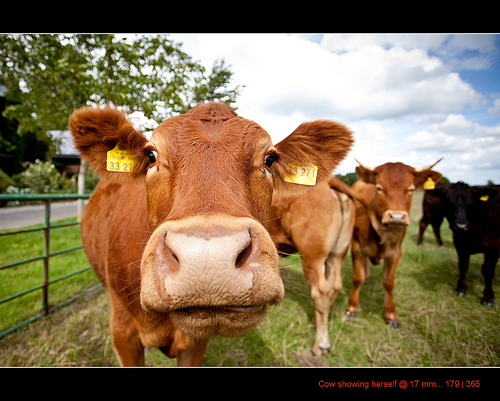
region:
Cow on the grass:
[332, 146, 452, 331]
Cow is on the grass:
[336, 146, 444, 326]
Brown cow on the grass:
[335, 151, 442, 331]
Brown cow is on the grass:
[339, 147, 445, 330]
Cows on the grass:
[61, 85, 498, 365]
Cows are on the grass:
[38, 92, 498, 367]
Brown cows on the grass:
[60, 98, 448, 368]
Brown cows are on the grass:
[57, 97, 447, 372]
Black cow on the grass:
[427, 170, 499, 310]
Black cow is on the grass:
[435, 175, 498, 309]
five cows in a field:
[3, 99, 498, 364]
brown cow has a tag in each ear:
[68, 100, 356, 364]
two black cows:
[415, 178, 499, 308]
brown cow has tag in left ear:
[348, 155, 445, 330]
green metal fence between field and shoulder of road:
[1, 192, 110, 367]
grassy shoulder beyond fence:
[0, 192, 102, 340]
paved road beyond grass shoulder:
[0, 201, 99, 334]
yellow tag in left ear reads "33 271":
[268, 119, 353, 213]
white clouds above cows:
[416, 112, 498, 310]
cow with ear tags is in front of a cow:
[66, 99, 358, 368]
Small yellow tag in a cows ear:
[88, 137, 145, 183]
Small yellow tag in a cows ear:
[277, 157, 324, 201]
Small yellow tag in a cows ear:
[413, 173, 434, 193]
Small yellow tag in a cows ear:
[473, 190, 487, 203]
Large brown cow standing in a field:
[275, 143, 357, 352]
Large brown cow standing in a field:
[350, 143, 420, 330]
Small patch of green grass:
[34, 324, 89, 361]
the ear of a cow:
[63, 101, 144, 183]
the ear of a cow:
[274, 117, 355, 203]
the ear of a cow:
[350, 162, 377, 189]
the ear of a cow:
[418, 165, 446, 195]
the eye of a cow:
[137, 136, 163, 178]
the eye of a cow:
[257, 139, 286, 181]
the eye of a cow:
[369, 177, 388, 198]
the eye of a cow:
[405, 176, 420, 201]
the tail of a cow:
[331, 174, 384, 226]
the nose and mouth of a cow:
[135, 216, 292, 339]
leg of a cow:
[118, 329, 153, 367]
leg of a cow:
[175, 338, 212, 373]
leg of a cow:
[307, 278, 342, 338]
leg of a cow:
[335, 251, 373, 318]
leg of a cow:
[372, 259, 410, 317]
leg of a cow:
[408, 213, 430, 244]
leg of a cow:
[430, 205, 454, 250]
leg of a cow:
[444, 252, 478, 297]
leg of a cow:
[474, 248, 498, 315]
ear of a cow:
[275, 105, 367, 196]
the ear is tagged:
[94, 126, 192, 213]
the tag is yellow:
[92, 148, 142, 198]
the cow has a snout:
[94, 175, 321, 345]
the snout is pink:
[167, 224, 263, 329]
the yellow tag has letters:
[96, 138, 148, 179]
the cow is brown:
[47, 78, 359, 361]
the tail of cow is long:
[334, 171, 391, 250]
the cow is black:
[422, 175, 499, 312]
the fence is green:
[0, 186, 99, 327]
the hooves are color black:
[336, 306, 406, 329]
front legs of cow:
[343, 254, 407, 331]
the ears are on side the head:
[349, 158, 447, 192]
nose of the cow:
[148, 226, 262, 273]